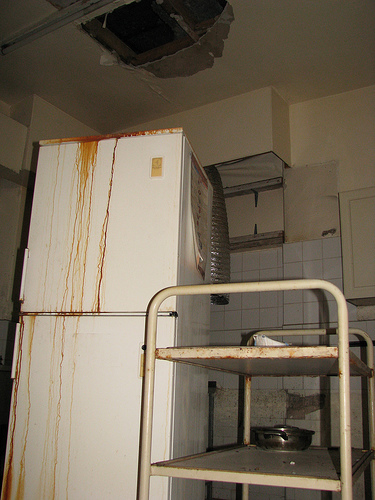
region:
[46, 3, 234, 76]
Ceiling has a hole in it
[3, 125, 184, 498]
rust runs down the fridge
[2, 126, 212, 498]
The fridge is white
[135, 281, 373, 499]
The shelves are metal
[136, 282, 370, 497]
The shelves show signs of rust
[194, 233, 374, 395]
The back wall was tiled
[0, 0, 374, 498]
The room is in shambles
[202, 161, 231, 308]
Grey ducting falling from ceiling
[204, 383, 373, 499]
Wall is torn apart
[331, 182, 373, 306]
Cabinet is still on wall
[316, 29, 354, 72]
part of the ceiling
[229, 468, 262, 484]
edge of a shelf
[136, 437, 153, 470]
part of a stand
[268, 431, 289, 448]
part of a hotpot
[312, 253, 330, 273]
part of a wall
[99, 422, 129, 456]
part of a fridge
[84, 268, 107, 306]
part pf some dirt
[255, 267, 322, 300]
edge of a bed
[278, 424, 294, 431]
lid of the hot pot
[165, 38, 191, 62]
edge of a ceiling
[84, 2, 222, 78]
hole in kitchen ceiling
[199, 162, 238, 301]
hanging silver duct behind refrigerator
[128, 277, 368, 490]
rusted white cart next to refrigerator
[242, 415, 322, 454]
metal pot on cart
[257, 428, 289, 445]
handle on metal pot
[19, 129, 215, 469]
refrigerator moved away from wall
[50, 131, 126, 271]
rust colored drippings on front of freezer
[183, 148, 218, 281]
paper attached to side of refrigerator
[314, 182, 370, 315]
cabinet attached to wall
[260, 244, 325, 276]
white tile on kitchen wall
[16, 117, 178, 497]
A dirty white refrigerator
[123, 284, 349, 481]
A dirty white cart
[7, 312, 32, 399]
The handle of a refrigerator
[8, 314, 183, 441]
The door of a refrigerator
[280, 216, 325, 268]
White tiles on a wall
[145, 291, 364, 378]
The top shelf of a cart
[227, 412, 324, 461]
A metal pan on a shelf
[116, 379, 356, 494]
A metal pan on a cart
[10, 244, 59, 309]
The handle of a freezer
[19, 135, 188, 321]
The dirty door of a freezer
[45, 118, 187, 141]
brown edge of fridge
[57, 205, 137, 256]
brown rust on front of fridge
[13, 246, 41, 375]
white door handles on fridge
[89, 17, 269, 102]
large hole in the ceiling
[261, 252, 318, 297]
white tiles on wall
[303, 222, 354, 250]
large black fastener on wall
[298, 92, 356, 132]
large tan walls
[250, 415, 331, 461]
shiny black cooking skillet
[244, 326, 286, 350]
white paper on cart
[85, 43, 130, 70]
white spot on ceiling